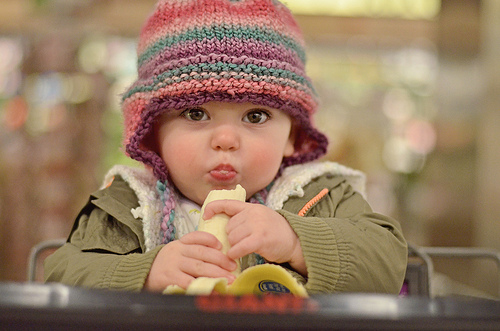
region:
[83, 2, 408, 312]
Small child eatting a banana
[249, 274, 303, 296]
Blue sticker on banana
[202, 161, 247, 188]
Red lps of a small chld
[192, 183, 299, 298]
Banana that has been eatten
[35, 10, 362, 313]
Small child in a shopping cart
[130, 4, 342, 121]
Multi colored crochetd hat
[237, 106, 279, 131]
Very pretty eye of a child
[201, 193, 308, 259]
Tiny hand of a child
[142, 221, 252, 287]
Tiny hand of a child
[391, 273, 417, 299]
Small purple part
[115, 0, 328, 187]
the hat is multi colored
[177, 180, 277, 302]
the toddler is holding a banana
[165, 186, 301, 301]
the banana is peeled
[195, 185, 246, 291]
the banana is yellow in color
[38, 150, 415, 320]
the toddler is wearing a jacket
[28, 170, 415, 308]
the jacket is taupe in color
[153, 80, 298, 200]
the toddler is looking head on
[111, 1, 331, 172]
the hat is knitted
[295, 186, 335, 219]
the zipper is orange in color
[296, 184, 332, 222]
the jacket has a zipper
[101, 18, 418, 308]
baby eating a banana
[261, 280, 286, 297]
sticker on the banana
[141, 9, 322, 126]
hat on baby's head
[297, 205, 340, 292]
cuff on baby's jacket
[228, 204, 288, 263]
hand of the baby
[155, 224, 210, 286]
hand of the baby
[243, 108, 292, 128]
eye of the baby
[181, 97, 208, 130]
eye of hte baby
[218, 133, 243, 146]
nose of the baby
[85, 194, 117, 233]
collar of the coat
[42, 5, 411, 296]
Child eating a banana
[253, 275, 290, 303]
Blue sticker on the peel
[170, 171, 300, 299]
The banana is yellow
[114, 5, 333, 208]
Child wearing a beanie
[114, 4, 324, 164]
The beanie is purple, green and pink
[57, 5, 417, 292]
Child wearing a green jacket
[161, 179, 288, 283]
The child is holding the banana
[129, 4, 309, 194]
The child has brown eyes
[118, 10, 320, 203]
The child is staring at the camera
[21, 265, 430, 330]
Silver bar in front of child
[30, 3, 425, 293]
a girl eating a banana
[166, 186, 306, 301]
a peeled banana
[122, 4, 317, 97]
knitted cap on head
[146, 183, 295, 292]
hands holding a banana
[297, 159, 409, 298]
green jacket with hood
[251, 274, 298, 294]
label on banana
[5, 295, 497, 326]
a plastic bar on cart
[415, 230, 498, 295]
a metal bar on cart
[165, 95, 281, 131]
eyes of little girl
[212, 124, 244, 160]
nose of little girl